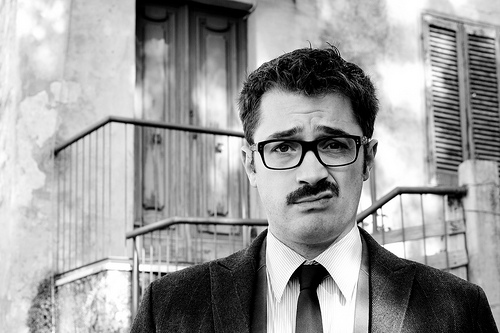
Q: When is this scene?
A: Daytime.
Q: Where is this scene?
A: Outside a house.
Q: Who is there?
A: Man.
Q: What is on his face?
A: Glasses.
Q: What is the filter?
A: Black and white.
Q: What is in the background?
A: House.